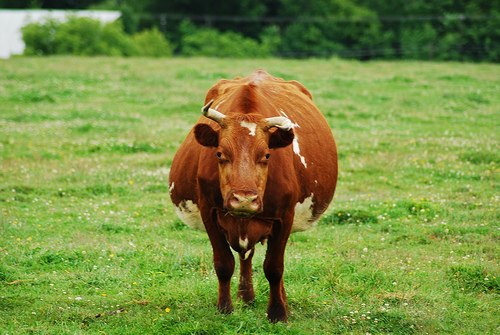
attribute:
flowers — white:
[44, 253, 156, 325]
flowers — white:
[22, 161, 62, 186]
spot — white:
[226, 110, 266, 155]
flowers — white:
[7, 227, 42, 259]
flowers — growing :
[344, 304, 379, 326]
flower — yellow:
[90, 217, 137, 282]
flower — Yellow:
[398, 253, 415, 266]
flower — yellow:
[121, 270, 147, 293]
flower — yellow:
[343, 151, 358, 163]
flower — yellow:
[375, 115, 443, 207]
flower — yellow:
[158, 304, 175, 316]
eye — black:
[252, 150, 272, 166]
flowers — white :
[346, 302, 390, 325]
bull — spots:
[162, 64, 344, 324]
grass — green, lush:
[7, 205, 130, 287]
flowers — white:
[45, 76, 129, 136]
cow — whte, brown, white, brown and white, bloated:
[164, 70, 340, 330]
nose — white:
[227, 192, 257, 203]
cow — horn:
[172, 70, 339, 316]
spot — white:
[290, 134, 309, 174]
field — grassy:
[13, 55, 131, 244]